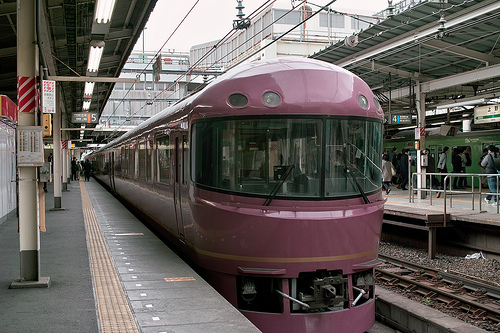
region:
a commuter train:
[25, 7, 445, 318]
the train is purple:
[225, 213, 367, 283]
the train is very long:
[107, 110, 394, 278]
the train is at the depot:
[74, 67, 368, 288]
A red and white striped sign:
[20, 81, 34, 106]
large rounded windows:
[208, 113, 418, 193]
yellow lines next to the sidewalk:
[81, 203, 103, 268]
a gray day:
[178, 5, 202, 29]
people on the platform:
[415, 127, 485, 198]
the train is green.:
[444, 131, 482, 168]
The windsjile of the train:
[182, 113, 380, 199]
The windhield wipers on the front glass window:
[265, 153, 374, 212]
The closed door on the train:
[163, 128, 188, 238]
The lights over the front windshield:
[222, 84, 382, 117]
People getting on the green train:
[384, 131, 499, 196]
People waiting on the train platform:
[69, 153, 97, 190]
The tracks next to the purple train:
[374, 243, 439, 295]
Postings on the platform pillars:
[15, 76, 60, 171]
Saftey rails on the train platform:
[412, 171, 497, 215]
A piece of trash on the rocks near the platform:
[455, 249, 488, 272]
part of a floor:
[133, 260, 166, 302]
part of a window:
[281, 144, 321, 206]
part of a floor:
[160, 260, 186, 303]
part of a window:
[296, 131, 326, 182]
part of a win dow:
[158, 261, 179, 296]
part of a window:
[338, 134, 365, 168]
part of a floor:
[121, 231, 146, 271]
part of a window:
[272, 118, 319, 129]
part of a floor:
[151, 270, 198, 321]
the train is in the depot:
[21, 10, 428, 322]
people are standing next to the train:
[68, 141, 93, 179]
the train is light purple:
[195, 61, 386, 268]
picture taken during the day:
[61, 48, 469, 326]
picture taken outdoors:
[34, 30, 472, 327]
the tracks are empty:
[401, 253, 466, 313]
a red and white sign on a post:
[18, 71, 42, 116]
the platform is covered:
[372, 25, 453, 67]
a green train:
[441, 128, 491, 186]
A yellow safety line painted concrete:
[80, 227, 131, 327]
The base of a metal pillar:
[2, 233, 61, 302]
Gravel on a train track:
[444, 247, 465, 268]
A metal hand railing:
[438, 167, 459, 211]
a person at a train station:
[474, 145, 499, 202]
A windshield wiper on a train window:
[260, 153, 301, 220]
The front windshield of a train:
[182, 104, 399, 234]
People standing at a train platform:
[68, 149, 98, 194]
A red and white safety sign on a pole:
[9, 68, 46, 123]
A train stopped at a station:
[118, 43, 434, 292]